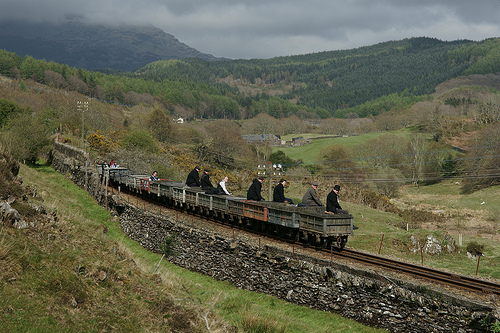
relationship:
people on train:
[147, 166, 345, 212] [100, 153, 354, 248]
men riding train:
[300, 180, 346, 214] [100, 153, 354, 248]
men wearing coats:
[300, 180, 346, 214] [302, 189, 343, 211]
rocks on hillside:
[3, 160, 52, 262] [3, 145, 269, 332]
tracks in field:
[110, 183, 496, 297] [6, 130, 499, 329]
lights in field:
[73, 93, 94, 151] [6, 130, 499, 329]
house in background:
[175, 115, 189, 127] [8, 16, 483, 149]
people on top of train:
[147, 166, 345, 212] [100, 153, 354, 248]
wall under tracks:
[121, 207, 491, 330] [110, 183, 496, 297]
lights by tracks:
[73, 93, 94, 151] [110, 183, 496, 297]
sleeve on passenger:
[219, 180, 230, 195] [214, 171, 231, 197]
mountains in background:
[7, 3, 493, 127] [8, 16, 483, 149]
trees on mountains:
[146, 47, 462, 121] [7, 3, 493, 127]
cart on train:
[241, 199, 270, 221] [100, 153, 354, 248]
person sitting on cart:
[245, 173, 270, 201] [241, 199, 270, 221]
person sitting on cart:
[271, 176, 291, 203] [267, 198, 299, 231]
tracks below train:
[110, 183, 496, 297] [100, 153, 354, 248]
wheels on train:
[270, 221, 351, 251] [100, 153, 354, 248]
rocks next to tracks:
[3, 160, 52, 262] [110, 183, 496, 297]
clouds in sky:
[3, 5, 494, 54] [2, 5, 498, 87]